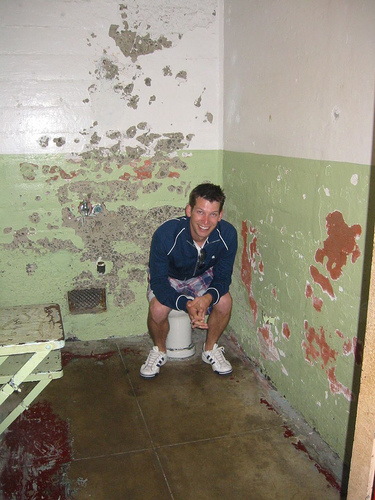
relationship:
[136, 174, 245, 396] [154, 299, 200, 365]
man using toilet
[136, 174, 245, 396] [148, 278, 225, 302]
man has shorts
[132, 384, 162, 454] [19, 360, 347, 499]
line on floor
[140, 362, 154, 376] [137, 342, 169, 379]
front of shoe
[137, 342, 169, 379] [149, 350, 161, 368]
shoe has laces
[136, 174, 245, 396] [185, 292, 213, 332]
man has hand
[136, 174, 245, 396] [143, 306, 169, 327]
man has knee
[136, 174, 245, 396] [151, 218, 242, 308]
man has jacket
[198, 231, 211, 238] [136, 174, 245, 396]
chin on man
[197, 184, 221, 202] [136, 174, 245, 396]
hair of man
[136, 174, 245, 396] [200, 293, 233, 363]
man has leg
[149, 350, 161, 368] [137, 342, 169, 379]
laces on shoe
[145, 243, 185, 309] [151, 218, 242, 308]
sleeve of jacket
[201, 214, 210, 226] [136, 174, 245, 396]
nose of man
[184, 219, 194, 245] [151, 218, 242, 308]
collar of jacket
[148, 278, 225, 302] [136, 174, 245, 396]
shorts on man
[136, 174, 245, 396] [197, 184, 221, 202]
man has hair